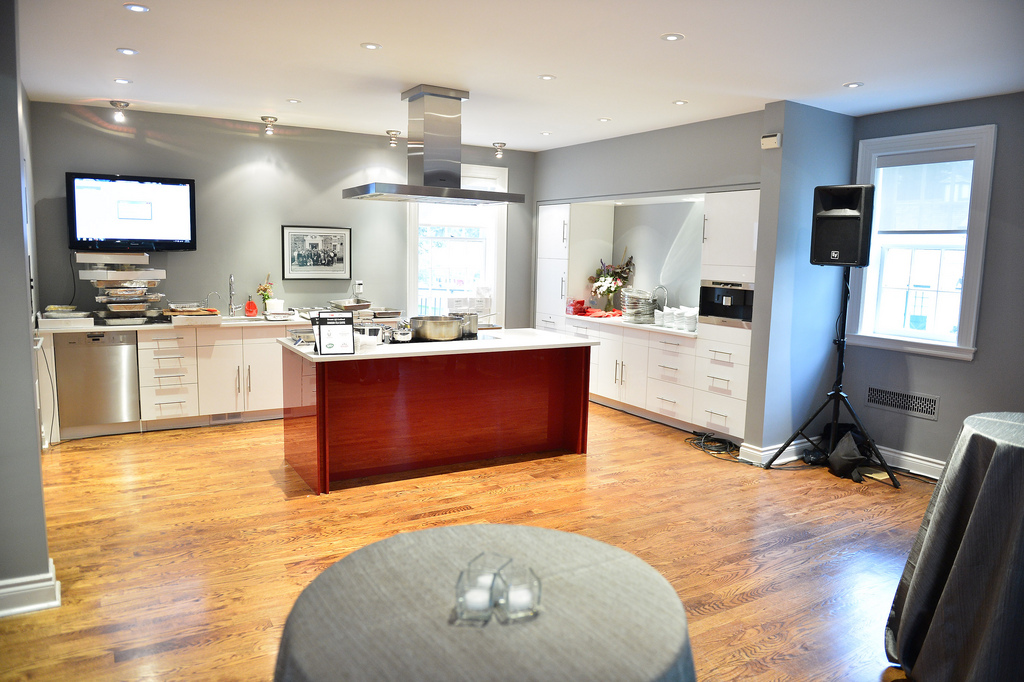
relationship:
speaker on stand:
[814, 178, 871, 269] [765, 267, 897, 494]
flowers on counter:
[577, 238, 641, 308] [531, 225, 737, 372]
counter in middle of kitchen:
[288, 329, 597, 468] [0, 3, 1021, 677]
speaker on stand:
[815, 178, 872, 269] [794, 316, 870, 472]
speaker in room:
[815, 178, 872, 269] [0, 3, 1024, 678]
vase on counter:
[606, 290, 620, 316] [564, 297, 757, 471]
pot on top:
[420, 317, 455, 343] [280, 313, 595, 490]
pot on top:
[454, 310, 474, 337] [280, 313, 595, 490]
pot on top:
[383, 321, 410, 339] [280, 313, 595, 490]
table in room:
[322, 541, 631, 671] [0, 3, 1024, 678]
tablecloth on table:
[899, 440, 1014, 654] [880, 408, 1021, 678]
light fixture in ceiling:
[104, 101, 128, 127] [20, 0, 1022, 155]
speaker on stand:
[814, 178, 871, 269] [763, 395, 903, 485]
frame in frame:
[281, 223, 357, 278] [271, 217, 367, 297]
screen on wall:
[72, 173, 197, 246] [26, 99, 540, 331]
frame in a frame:
[281, 223, 357, 278] [275, 221, 360, 291]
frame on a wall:
[275, 221, 360, 291] [26, 99, 540, 331]